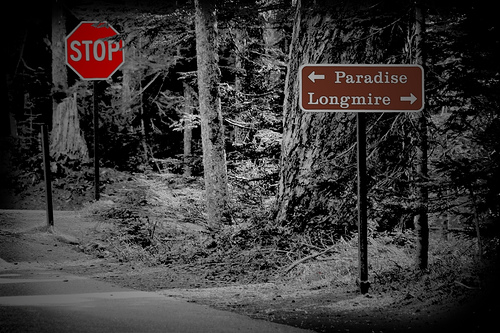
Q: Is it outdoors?
A: Yes, it is outdoors.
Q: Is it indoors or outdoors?
A: It is outdoors.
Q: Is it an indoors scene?
A: No, it is outdoors.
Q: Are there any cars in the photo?
A: No, there are no cars.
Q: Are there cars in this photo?
A: No, there are no cars.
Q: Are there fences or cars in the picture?
A: No, there are no cars or fences.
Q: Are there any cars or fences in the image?
A: No, there are no cars or fences.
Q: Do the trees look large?
A: Yes, the trees are large.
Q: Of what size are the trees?
A: The trees are large.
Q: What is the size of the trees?
A: The trees are large.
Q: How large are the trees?
A: The trees are large.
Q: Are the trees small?
A: No, the trees are large.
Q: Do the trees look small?
A: No, the trees are large.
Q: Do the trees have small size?
A: No, the trees are large.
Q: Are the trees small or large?
A: The trees are large.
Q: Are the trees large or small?
A: The trees are large.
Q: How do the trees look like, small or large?
A: The trees are large.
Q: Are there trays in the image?
A: No, there are no trays.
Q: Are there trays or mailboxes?
A: No, there are no trays or mailboxes.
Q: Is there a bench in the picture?
A: No, there are no benches.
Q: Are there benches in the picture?
A: No, there are no benches.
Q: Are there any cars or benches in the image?
A: No, there are no benches or cars.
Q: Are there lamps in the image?
A: No, there are no lamps.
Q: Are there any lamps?
A: No, there are no lamps.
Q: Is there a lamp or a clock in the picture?
A: No, there are no lamps or clocks.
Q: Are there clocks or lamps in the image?
A: No, there are no lamps or clocks.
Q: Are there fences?
A: No, there are no fences.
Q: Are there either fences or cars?
A: No, there are no fences or cars.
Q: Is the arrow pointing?
A: Yes, the arrow is pointing.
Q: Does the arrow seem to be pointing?
A: Yes, the arrow is pointing.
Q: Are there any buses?
A: No, there are no buses.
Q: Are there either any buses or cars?
A: No, there are no buses or cars.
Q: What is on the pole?
A: The sign is on the pole.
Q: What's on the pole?
A: The sign is on the pole.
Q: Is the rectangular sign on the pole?
A: Yes, the sign is on the pole.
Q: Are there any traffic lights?
A: No, there are no traffic lights.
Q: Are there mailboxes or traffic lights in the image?
A: No, there are no traffic lights or mailboxes.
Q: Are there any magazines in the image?
A: No, there are no magazines.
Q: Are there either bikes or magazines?
A: No, there are no magazines or bikes.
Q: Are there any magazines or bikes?
A: No, there are no magazines or bikes.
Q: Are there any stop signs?
A: Yes, there is a stop sign.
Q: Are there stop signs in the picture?
A: Yes, there is a stop sign.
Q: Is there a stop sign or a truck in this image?
A: Yes, there is a stop sign.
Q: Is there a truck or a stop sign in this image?
A: Yes, there is a stop sign.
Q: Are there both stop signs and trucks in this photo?
A: No, there is a stop sign but no trucks.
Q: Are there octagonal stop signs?
A: Yes, there is an octagonal stop sign.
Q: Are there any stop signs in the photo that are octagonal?
A: Yes, there is a stop sign that is octagonal.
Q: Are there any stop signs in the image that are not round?
A: Yes, there is a octagonal stop sign.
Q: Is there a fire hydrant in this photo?
A: No, there are no fire hydrants.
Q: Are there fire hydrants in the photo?
A: No, there are no fire hydrants.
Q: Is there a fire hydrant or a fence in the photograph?
A: No, there are no fire hydrants or fences.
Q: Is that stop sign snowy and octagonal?
A: Yes, the stop sign is snowy and octagonal.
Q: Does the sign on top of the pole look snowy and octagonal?
A: Yes, the stop sign is snowy and octagonal.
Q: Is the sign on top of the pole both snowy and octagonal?
A: Yes, the stop sign is snowy and octagonal.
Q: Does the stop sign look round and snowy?
A: No, the stop sign is snowy but octagonal.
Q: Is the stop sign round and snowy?
A: No, the stop sign is snowy but octagonal.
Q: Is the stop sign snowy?
A: Yes, the stop sign is snowy.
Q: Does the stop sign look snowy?
A: Yes, the stop sign is snowy.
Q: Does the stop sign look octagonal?
A: Yes, the stop sign is octagonal.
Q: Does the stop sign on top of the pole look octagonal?
A: Yes, the stop sign is octagonal.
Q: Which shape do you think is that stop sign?
A: The stop sign is octagonal.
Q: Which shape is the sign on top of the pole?
A: The stop sign is octagonal.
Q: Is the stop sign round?
A: No, the stop sign is octagonal.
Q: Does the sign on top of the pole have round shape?
A: No, the stop sign is octagonal.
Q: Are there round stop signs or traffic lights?
A: No, there is a stop sign but it is octagonal.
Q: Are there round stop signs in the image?
A: No, there is a stop sign but it is octagonal.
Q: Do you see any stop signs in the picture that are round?
A: No, there is a stop sign but it is octagonal.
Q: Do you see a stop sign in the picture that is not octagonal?
A: No, there is a stop sign but it is octagonal.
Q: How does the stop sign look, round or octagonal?
A: The stop sign is octagonal.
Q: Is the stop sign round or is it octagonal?
A: The stop sign is octagonal.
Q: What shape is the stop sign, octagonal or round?
A: The stop sign is octagonal.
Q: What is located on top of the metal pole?
A: The stop sign is on top of the pole.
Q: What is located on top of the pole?
A: The stop sign is on top of the pole.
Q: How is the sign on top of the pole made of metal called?
A: The sign is a stop sign.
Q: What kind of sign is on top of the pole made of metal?
A: The sign is a stop sign.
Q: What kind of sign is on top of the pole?
A: The sign is a stop sign.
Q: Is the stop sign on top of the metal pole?
A: Yes, the stop sign is on top of the pole.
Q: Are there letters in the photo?
A: Yes, there are letters.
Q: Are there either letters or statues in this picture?
A: Yes, there are letters.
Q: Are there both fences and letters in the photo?
A: No, there are letters but no fences.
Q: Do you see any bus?
A: No, there are no buses.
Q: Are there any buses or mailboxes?
A: No, there are no buses or mailboxes.